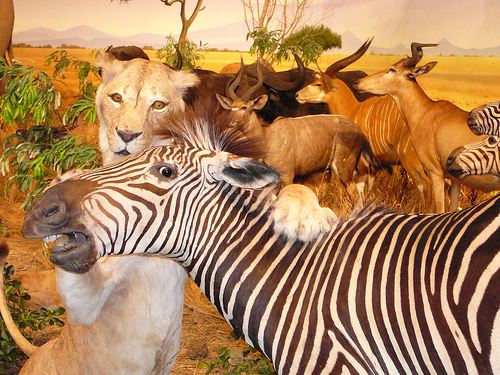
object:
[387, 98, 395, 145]
stripes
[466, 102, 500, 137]
animal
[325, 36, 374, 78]
horns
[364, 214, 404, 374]
stripes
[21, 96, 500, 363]
zebra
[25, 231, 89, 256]
mouth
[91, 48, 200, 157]
lion head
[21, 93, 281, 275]
zebra head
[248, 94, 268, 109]
antler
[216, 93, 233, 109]
antler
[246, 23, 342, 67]
tree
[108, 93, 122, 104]
eyes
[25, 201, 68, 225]
nose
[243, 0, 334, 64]
tree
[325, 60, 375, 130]
no sentence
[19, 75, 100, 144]
mound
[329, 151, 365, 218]
back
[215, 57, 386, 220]
antelope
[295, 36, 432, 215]
antelope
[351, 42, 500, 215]
antelope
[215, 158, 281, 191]
ears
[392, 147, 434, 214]
back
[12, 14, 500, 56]
mountain range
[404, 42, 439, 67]
horns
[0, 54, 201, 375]
cat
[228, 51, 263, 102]
antlers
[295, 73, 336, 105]
head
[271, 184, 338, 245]
paw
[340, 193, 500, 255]
back